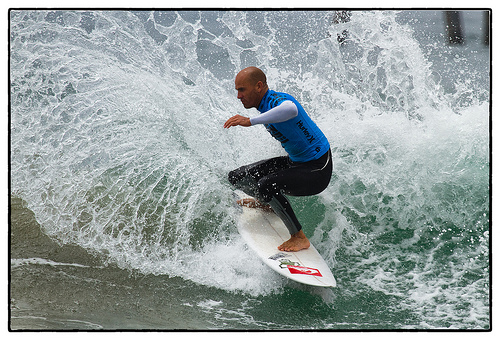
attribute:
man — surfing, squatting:
[223, 66, 332, 253]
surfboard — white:
[227, 187, 337, 288]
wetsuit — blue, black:
[229, 89, 331, 234]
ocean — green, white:
[11, 8, 490, 330]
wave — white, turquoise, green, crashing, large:
[8, 36, 489, 307]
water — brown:
[11, 194, 213, 331]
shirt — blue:
[256, 89, 329, 162]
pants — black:
[229, 149, 333, 235]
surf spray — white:
[280, 9, 490, 107]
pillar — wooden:
[438, 9, 466, 47]